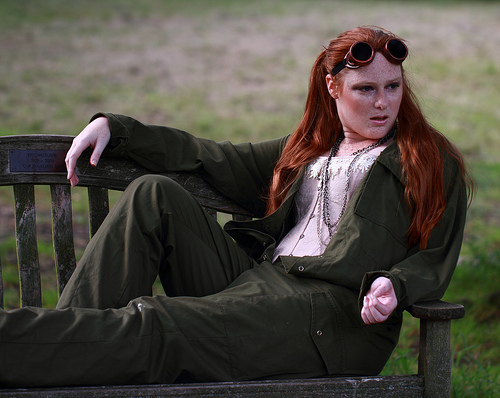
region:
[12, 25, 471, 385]
the red headed female on the bench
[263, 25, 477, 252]
the female's red head on her hair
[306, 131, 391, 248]
the necklace around the female's neck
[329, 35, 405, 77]
the goggles on the female's head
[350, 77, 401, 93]
the eyes on the female's face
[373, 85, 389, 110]
the nose on the female's face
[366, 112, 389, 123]
the mouth on the female's face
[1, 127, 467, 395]
the bench the female is sitting on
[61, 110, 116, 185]
the female's right hand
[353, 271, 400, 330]
the female's left hand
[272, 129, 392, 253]
necklaces on a woman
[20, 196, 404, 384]
green cargo pants on a woman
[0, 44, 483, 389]
a woman sitting on a bench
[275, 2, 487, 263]
a red haired girl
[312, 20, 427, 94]
goggles on a woman's head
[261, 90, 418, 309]
a white tanktop under shirt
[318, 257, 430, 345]
a womans hand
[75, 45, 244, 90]
a patch of dead grass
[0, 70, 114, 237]
a wooden bench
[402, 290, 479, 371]
wooden arm of the bench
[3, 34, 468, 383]
model posing on bench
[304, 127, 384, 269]
jewelry model is wearing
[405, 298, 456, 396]
armrest of bench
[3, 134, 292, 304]
back of bench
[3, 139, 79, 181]
small plaque on back of bench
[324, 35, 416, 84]
model's red and black glasses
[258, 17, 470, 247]
the model's long red hair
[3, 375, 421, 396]
the seat of the bench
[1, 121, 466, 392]
the matching outfit the model is wearing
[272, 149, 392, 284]
the model's white blouse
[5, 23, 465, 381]
woman posing on bench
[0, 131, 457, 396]
bench woman is posing on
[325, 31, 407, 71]
sunglasses of woman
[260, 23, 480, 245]
woman's red hair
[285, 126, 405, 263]
necklaces the woman is wearing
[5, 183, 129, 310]
back slats of the bench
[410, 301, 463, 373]
armrest of the bench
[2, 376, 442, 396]
seat of the bench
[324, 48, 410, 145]
woman's face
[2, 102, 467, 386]
the matching jacket and pants of the woman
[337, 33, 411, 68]
goggles on woman's head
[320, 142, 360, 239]
necklaces around woman's neck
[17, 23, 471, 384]
woman sitting on a bench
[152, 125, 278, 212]
part of woman's green jacket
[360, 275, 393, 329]
woman's right hand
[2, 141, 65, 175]
sign on the bench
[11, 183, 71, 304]
wooden slabs on the bench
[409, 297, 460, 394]
arm of the bench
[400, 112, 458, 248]
peice of woman's red hair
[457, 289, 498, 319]
green grass beside bench